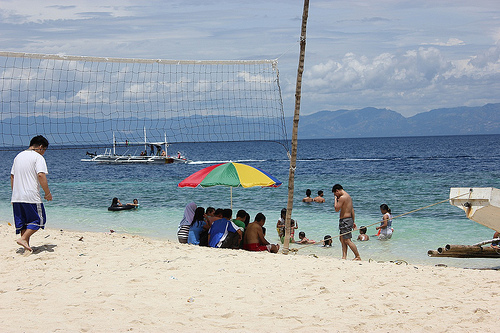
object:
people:
[243, 212, 279, 254]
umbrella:
[178, 162, 283, 188]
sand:
[3, 225, 499, 332]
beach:
[1, 185, 496, 329]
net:
[1, 49, 291, 165]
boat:
[79, 126, 174, 165]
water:
[72, 152, 226, 190]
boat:
[446, 186, 497, 233]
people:
[332, 184, 363, 262]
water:
[254, 198, 445, 263]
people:
[127, 199, 141, 209]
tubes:
[107, 206, 125, 211]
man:
[9, 135, 52, 254]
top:
[8, 149, 48, 204]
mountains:
[406, 100, 497, 138]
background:
[3, 43, 498, 134]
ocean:
[1, 133, 499, 269]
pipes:
[444, 243, 499, 252]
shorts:
[12, 202, 46, 235]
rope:
[289, 193, 466, 254]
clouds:
[287, 46, 495, 93]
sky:
[2, 4, 496, 103]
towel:
[184, 202, 197, 222]